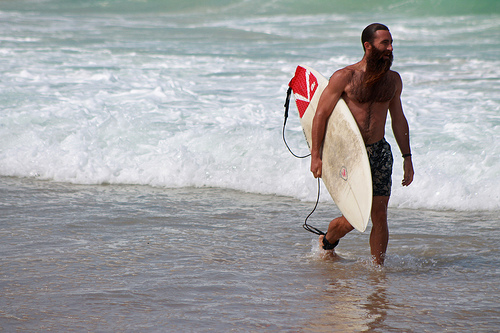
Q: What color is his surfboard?
A: Mostly white.